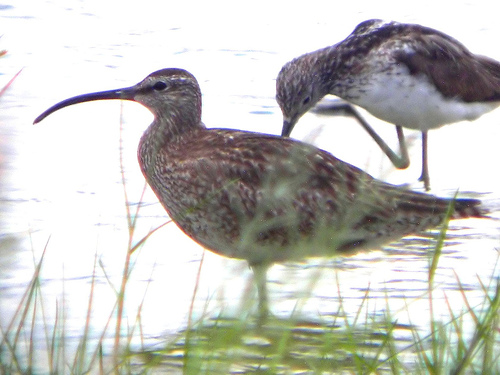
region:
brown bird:
[52, 49, 280, 230]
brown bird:
[261, 13, 466, 141]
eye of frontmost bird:
[152, 77, 168, 94]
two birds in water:
[26, 12, 498, 309]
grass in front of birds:
[2, 156, 498, 373]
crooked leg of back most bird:
[318, 91, 413, 174]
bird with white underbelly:
[255, 2, 495, 193]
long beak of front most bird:
[28, 77, 125, 130]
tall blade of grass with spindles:
[100, 87, 172, 373]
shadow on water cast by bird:
[148, 287, 385, 373]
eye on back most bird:
[294, 89, 313, 108]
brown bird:
[41, 59, 248, 254]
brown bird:
[250, 2, 490, 150]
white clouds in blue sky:
[115, 22, 156, 50]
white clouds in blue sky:
[237, 12, 277, 44]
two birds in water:
[96, 25, 452, 256]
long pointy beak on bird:
[25, 76, 139, 137]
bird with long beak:
[34, 53, 280, 287]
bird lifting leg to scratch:
[324, 67, 445, 185]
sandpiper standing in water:
[58, 63, 352, 331]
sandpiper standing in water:
[271, 10, 475, 200]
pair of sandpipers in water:
[55, 7, 449, 309]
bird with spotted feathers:
[90, 45, 327, 310]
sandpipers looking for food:
[83, 54, 390, 291]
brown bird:
[42, 72, 229, 227]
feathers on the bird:
[184, 168, 249, 217]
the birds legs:
[381, 129, 431, 178]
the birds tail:
[428, 191, 493, 229]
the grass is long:
[266, 298, 401, 359]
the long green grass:
[275, 269, 404, 372]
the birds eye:
[150, 78, 170, 95]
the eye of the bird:
[297, 95, 315, 108]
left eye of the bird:
[300, 95, 313, 105]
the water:
[61, 214, 110, 284]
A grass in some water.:
[416, 191, 453, 352]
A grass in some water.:
[396, 293, 425, 370]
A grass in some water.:
[443, 258, 488, 355]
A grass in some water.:
[336, 281, 370, 371]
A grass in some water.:
[88, 80, 163, 371]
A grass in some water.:
[124, 248, 163, 373]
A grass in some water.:
[68, 243, 101, 361]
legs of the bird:
[233, 265, 278, 327]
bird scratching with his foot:
[271, 16, 496, 193]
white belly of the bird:
[350, 57, 477, 126]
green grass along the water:
[19, 217, 487, 371]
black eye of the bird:
[153, 77, 168, 94]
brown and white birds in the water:
[21, 27, 498, 322]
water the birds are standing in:
[3, 15, 498, 356]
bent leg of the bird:
[320, 95, 415, 175]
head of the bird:
[133, 65, 201, 120]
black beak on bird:
[26, 87, 131, 121]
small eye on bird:
[152, 80, 167, 92]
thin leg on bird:
[248, 260, 275, 333]